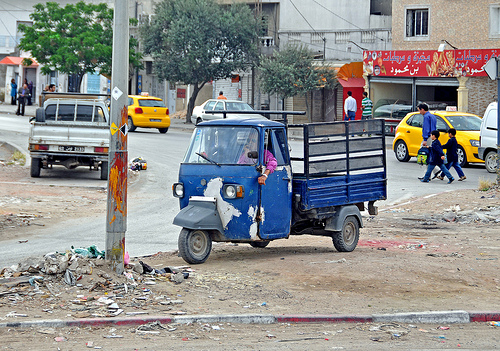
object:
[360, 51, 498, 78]
sign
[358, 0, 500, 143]
building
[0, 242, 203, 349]
debris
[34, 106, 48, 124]
tire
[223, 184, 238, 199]
light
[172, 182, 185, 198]
light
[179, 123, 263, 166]
windshield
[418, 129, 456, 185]
kids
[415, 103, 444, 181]
man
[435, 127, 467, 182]
boy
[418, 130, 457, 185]
boy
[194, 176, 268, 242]
paint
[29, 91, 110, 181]
pickup truck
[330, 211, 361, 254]
wheel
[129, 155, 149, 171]
garbage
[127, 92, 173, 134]
cab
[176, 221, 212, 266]
front wheel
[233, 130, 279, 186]
person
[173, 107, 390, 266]
vehicle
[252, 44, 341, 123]
trees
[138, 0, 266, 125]
trees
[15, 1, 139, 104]
trees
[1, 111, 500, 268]
street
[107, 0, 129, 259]
pole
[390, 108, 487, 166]
car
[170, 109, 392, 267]
pickup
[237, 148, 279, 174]
clothes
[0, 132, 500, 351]
ground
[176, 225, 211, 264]
wheel